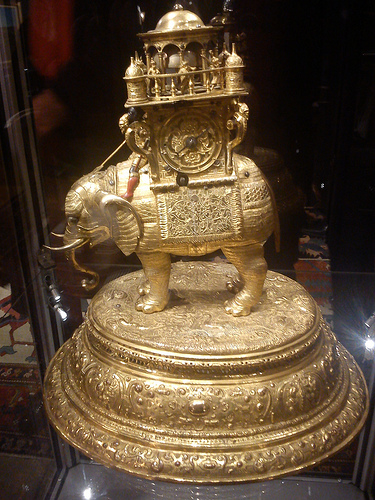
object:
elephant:
[41, 151, 281, 319]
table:
[38, 309, 375, 497]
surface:
[65, 450, 373, 500]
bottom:
[43, 256, 371, 485]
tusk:
[41, 238, 84, 253]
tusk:
[51, 232, 65, 238]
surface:
[247, 0, 375, 306]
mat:
[0, 368, 48, 463]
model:
[118, 0, 251, 188]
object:
[20, 6, 76, 82]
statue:
[42, 263, 370, 487]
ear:
[102, 196, 142, 257]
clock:
[156, 108, 222, 180]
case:
[0, 0, 374, 492]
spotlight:
[339, 324, 375, 363]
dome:
[40, 254, 371, 482]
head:
[60, 166, 144, 292]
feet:
[134, 249, 268, 317]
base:
[42, 259, 371, 482]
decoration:
[117, 1, 255, 191]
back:
[113, 149, 252, 208]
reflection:
[247, 85, 308, 211]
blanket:
[155, 183, 242, 244]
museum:
[0, 0, 375, 500]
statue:
[40, 1, 370, 483]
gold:
[38, 1, 368, 485]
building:
[127, 2, 252, 189]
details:
[81, 0, 277, 260]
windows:
[0, 0, 375, 500]